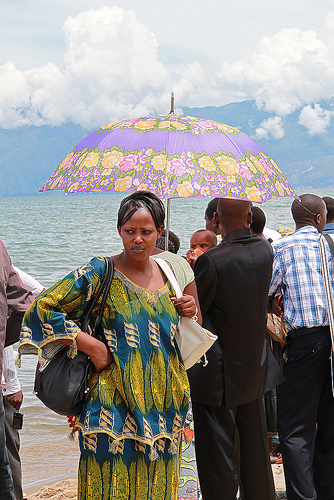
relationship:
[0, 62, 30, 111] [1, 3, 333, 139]
cloud in sky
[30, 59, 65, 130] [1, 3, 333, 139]
cloud in sky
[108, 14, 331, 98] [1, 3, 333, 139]
cloud in sky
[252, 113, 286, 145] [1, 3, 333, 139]
cloud in sky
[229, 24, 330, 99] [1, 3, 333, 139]
cloud in sky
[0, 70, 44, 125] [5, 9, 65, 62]
cloud in sky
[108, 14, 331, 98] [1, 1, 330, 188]
cloud in sky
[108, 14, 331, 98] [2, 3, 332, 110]
cloud in sky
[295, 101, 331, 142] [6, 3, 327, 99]
cloud in sky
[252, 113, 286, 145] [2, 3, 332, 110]
cloud in sky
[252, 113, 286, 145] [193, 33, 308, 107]
cloud in sky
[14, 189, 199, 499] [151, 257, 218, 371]
she holding purse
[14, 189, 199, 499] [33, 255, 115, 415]
she holding purse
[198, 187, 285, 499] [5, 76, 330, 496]
people at event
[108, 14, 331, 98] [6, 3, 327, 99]
cloud in sky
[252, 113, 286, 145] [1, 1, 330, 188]
cloud in sky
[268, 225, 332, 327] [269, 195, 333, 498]
shirt worn by man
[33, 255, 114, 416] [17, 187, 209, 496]
handbag held by woman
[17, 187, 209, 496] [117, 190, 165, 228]
woman with black hair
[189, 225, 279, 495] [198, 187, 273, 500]
suit on people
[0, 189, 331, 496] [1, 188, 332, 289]
crowd front ocean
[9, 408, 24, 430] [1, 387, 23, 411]
camera in hand